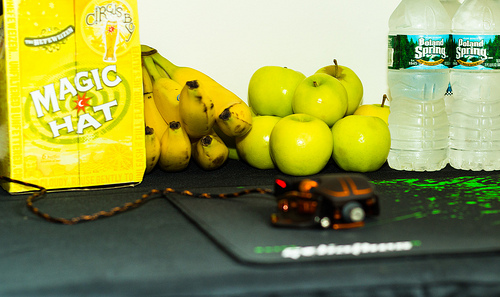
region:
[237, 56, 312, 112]
Medium sized green apple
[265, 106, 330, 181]
Medium sized green apple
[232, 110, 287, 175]
Medium sized green apple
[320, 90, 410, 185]
Medium sized green apple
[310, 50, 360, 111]
Medium sized green apple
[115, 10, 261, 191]
bunch of yellow bananas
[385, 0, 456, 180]
Clear bottle of water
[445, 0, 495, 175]
Clear bottle of water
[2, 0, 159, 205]
yellow cardboard carton of beverages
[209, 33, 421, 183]
Bunch of green apples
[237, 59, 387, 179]
7 green apples in a pile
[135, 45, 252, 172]
5 bananas getting ripe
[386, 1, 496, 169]
2 cold Poland spring water bottles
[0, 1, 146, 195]
the Hefeweizen Circus Boy Magic Hat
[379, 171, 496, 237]
neon green splatter on black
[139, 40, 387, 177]
green apples and a bunch of yellow bananas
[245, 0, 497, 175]
cold water bottles and green apples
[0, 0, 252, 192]
Magic Hat and a bunch of bananas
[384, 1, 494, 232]
cold water bottles above green spatter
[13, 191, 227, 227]
orange and black string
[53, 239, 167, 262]
smooth gray table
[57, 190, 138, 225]
brown and orange cord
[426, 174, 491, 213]
green paint on table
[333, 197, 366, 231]
gray and white button on toy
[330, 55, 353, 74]
little stem on golden delicious apple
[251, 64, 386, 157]
bunch of green apples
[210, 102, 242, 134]
black spots on banana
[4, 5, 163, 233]
large yellow bag with white markings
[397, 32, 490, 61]
blue label on water bottle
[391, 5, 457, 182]
ice cold water bottle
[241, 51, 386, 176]
A few yellow apples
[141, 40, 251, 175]
A bunch of ripe bananas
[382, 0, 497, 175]
A couple of bottles of water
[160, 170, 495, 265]
A gray mouse pad splattered with green paint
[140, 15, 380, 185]
Fruit on a counter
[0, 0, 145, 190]
A carton of "Magic Hat" beer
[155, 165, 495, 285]
Mouse and mouse pad on a counter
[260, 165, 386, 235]
Brown and orange computer mouse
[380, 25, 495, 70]
Poland Spring labels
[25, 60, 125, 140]
"Magic Hat" logo on a carton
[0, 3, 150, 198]
beer box, in yellow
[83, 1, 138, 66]
CIRCUS BOY+depicted yellow beer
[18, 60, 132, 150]
MAGIC HAT in a swirly looking circle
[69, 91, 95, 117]
C in a bright red burst of star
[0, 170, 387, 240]
orange+black tattoo gun [i think] with orange+black cord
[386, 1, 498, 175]
poland spring water looks icy but yellowy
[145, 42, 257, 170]
bunch of bananas just beginning to age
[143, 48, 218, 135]
top banana, above the rest, & pointier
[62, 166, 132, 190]
ROUSE GENTLY [on yellow box]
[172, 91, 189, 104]
? visible chiquita banana label on top banana